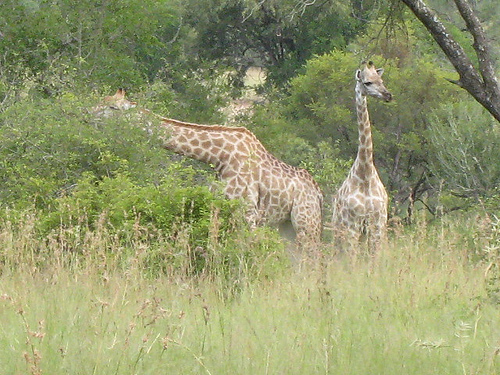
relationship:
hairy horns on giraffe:
[360, 58, 378, 71] [331, 59, 393, 258]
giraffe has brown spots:
[92, 93, 326, 267] [224, 138, 259, 172]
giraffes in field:
[84, 61, 395, 261] [4, 3, 496, 372]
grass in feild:
[9, 208, 499, 372] [4, 3, 496, 372]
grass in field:
[9, 208, 499, 372] [4, 3, 496, 372]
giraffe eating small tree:
[92, 93, 326, 267] [0, 76, 140, 189]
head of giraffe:
[351, 62, 392, 105] [331, 59, 393, 258]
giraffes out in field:
[84, 61, 395, 261] [4, 3, 496, 372]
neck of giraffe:
[131, 106, 240, 170] [92, 93, 326, 267]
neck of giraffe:
[355, 96, 380, 188] [331, 59, 393, 258]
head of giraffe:
[88, 89, 144, 129] [92, 93, 326, 267]